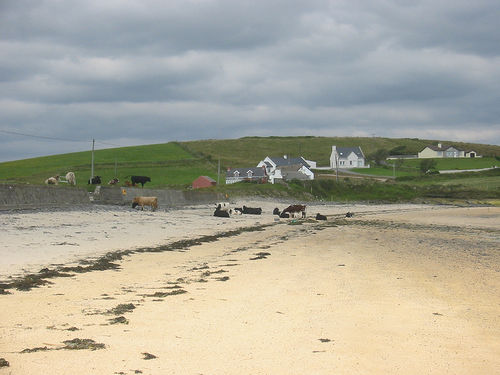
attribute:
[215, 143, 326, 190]
house — white, big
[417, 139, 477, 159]
house — big 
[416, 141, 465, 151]
roof — brown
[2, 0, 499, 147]
sky — cloudy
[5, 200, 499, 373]
beach — low tide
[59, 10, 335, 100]
sky — clouded, dark gray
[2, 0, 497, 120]
clouds — grey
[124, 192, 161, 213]
horse drinking — big , brown 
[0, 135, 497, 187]
hill — large , green , grassy 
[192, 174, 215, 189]
house — small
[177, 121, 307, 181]
hill — grassy